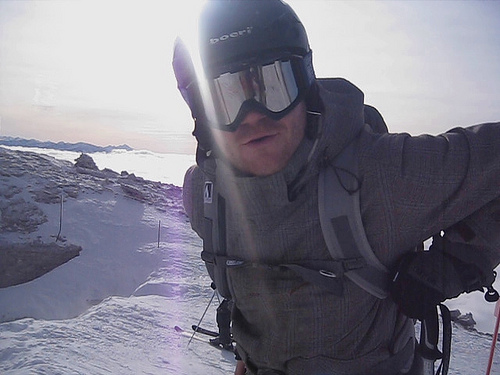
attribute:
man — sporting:
[166, 2, 499, 375]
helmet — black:
[166, 5, 327, 116]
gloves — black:
[397, 264, 450, 320]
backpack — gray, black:
[322, 141, 453, 324]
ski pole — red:
[192, 288, 218, 348]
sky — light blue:
[3, 2, 500, 153]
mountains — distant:
[2, 135, 130, 158]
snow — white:
[10, 146, 278, 374]